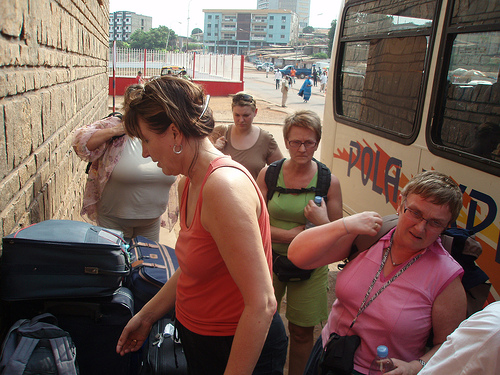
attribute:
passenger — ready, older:
[112, 73, 294, 373]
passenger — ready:
[208, 90, 286, 179]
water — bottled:
[368, 357, 395, 374]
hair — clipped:
[120, 74, 216, 145]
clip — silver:
[196, 93, 213, 121]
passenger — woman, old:
[254, 110, 348, 375]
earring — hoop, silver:
[171, 143, 185, 155]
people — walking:
[263, 63, 317, 108]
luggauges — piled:
[1, 218, 187, 374]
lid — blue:
[375, 344, 391, 358]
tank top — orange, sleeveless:
[173, 152, 276, 337]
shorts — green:
[265, 247, 331, 329]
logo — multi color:
[333, 136, 499, 311]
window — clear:
[332, 0, 440, 145]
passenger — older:
[287, 168, 472, 374]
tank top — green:
[263, 163, 335, 280]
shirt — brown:
[209, 124, 280, 186]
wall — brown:
[1, 1, 111, 238]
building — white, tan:
[109, 10, 154, 49]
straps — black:
[263, 156, 332, 212]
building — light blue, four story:
[202, 7, 300, 60]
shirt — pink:
[320, 219, 470, 373]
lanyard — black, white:
[350, 232, 427, 325]